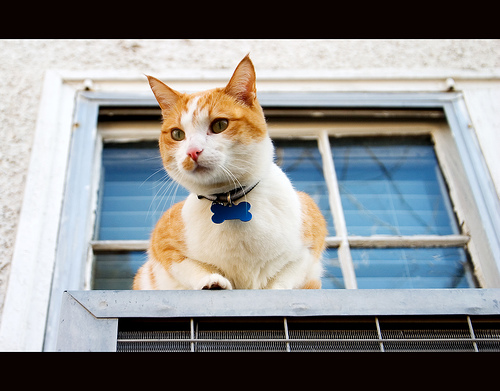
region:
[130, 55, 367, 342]
A brown and white cat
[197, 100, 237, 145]
A brown and white cat's eye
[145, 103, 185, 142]
A brown and white cat's eye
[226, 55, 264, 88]
A brown and white cat's ear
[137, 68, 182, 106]
A brown and white cat's ear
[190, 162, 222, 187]
A brown and white cat's mouth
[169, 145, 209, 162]
A brown and white cat's nose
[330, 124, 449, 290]
A clear glass window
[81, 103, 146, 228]
A clear glass window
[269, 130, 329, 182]
A clear glass window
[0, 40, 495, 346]
cat is sitting outside a window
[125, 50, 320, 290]
cat has a blue tag on her collar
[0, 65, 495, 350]
window frame is painted white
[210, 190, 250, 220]
pet name tag is blue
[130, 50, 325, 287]
cat is orange and white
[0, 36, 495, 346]
cat is sitting on an air vent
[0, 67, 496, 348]
window has blinds inside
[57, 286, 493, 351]
air vent is silver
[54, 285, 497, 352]
air vent is made of metal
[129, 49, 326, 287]
cat is furry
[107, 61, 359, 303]
a cat on an AC unit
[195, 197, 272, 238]
a blue tag on collar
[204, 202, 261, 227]
a blue bone on cat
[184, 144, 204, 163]
a small pink nose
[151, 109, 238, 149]
green eyes of cat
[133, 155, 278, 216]
white whiskers of cat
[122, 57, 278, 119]
two pointy ears of cat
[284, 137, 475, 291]
reflection of tree limbs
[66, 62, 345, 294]
an orange and white cat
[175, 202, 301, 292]
white chest of cat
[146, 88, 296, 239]
cat sitting on window a/c unit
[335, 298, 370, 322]
a/c unit is gray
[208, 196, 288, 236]
tag on collar is blue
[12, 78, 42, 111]
gray stucco on wall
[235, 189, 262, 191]
cat's collar is black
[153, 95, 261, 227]
cat is tan and white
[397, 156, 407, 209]
shiny pane of window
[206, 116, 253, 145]
cat has green eyes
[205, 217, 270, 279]
cat has white chest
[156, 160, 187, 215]
cat has white whiskers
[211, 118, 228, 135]
the eye of a cat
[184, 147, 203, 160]
the nose of a cat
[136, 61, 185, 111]
the ear of a cat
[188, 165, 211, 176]
the mouth of a cat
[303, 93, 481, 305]
a window of a house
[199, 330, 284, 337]
a mesh on the window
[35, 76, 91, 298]
the frame of a window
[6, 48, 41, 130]
the wall of a house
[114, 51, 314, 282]
a cat in the window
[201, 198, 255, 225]
a blue ornament on a cat's neck